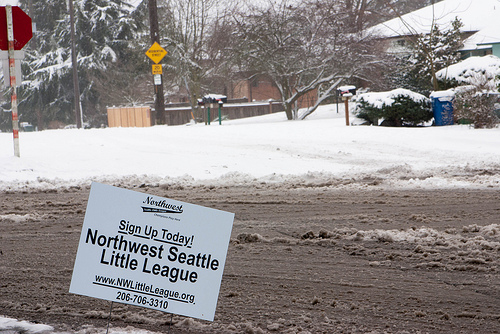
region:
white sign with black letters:
[65, 178, 237, 324]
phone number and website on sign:
[90, 271, 198, 309]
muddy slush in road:
[1, 166, 498, 331]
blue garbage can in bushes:
[426, 90, 455, 125]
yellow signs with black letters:
[143, 38, 167, 75]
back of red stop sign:
[1, 2, 36, 162]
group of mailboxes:
[193, 90, 229, 126]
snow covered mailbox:
[333, 81, 358, 126]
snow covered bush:
[352, 80, 432, 127]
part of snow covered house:
[346, 0, 499, 62]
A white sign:
[66, 176, 237, 322]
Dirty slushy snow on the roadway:
[0, 186, 496, 331]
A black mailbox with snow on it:
[336, 82, 356, 125]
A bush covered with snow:
[353, 88, 431, 128]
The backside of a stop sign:
[1, 4, 35, 159]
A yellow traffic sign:
[144, 39, 167, 76]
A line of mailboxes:
[194, 90, 226, 125]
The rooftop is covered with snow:
[348, 0, 498, 49]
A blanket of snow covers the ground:
[1, 98, 498, 183]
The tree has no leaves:
[213, 3, 400, 123]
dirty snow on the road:
[1, 188, 498, 332]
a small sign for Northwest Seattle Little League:
[64, 181, 237, 332]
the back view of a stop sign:
[0, 2, 39, 155]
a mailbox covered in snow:
[336, 83, 358, 125]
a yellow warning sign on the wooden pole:
[142, 40, 167, 75]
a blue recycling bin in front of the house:
[428, 89, 458, 126]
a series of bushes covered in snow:
[352, 50, 499, 126]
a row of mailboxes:
[196, 92, 226, 125]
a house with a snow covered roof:
[343, 0, 498, 88]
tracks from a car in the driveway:
[266, 138, 451, 175]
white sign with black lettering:
[66, 179, 233, 316]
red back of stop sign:
[2, 8, 31, 45]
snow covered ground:
[6, 119, 495, 179]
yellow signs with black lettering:
[142, 40, 172, 75]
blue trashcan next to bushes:
[425, 87, 455, 127]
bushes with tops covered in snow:
[350, 80, 423, 123]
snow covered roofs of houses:
[348, 2, 499, 52]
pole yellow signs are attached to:
[145, 1, 173, 127]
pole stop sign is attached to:
[2, 12, 24, 152]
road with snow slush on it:
[7, 184, 477, 330]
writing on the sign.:
[120, 287, 180, 298]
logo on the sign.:
[139, 196, 188, 216]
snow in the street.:
[347, 218, 425, 260]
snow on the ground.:
[106, 155, 158, 171]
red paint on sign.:
[17, 15, 30, 42]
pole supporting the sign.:
[9, 65, 21, 153]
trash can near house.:
[432, 93, 451, 122]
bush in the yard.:
[386, 102, 410, 119]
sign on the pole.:
[148, 43, 165, 60]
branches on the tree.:
[267, 24, 296, 46]